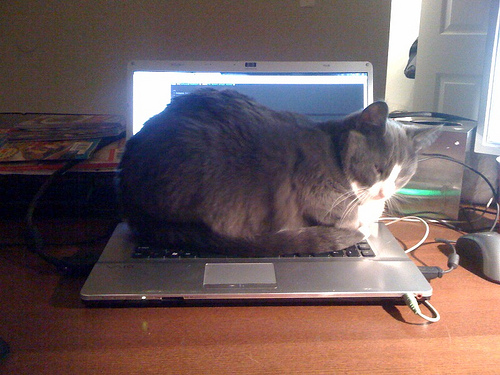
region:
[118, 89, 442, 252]
big cat standing on a laptop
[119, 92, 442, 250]
cat is gray and white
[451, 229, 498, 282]
black and gray mouse of a laptop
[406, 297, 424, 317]
green plug connected to laptop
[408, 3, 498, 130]
white door i the back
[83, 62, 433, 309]
gray laptop on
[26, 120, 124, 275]
black cable of laptop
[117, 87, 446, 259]
cat is lying on a laptop keyboard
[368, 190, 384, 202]
little pinky nose of cat sleeping on a laptop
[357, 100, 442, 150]
two small furry ears of a cat sleeping on a laptop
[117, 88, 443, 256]
white and gray furry cat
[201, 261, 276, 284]
gray laptop mouse pad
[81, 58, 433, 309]
Silver and black laptop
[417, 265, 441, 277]
gray USB plug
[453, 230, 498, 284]
Black and silver computer mouse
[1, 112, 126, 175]
Many different colored magazines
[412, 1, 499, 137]
White interior door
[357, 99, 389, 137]
Furry gray cat ear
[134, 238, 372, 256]
Black laptop computer keys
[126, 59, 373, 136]
Bright Laptop monitor screen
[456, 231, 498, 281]
gray computer mouse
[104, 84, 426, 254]
gray cat sitting on laptop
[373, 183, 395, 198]
white fur on cat's face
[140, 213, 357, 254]
long gray cat's tail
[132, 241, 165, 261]
black computer keys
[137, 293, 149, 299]
white light on computer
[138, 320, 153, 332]
light reflection on desk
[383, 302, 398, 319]
dark shadow from cord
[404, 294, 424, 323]
white cord in computer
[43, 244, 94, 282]
black cord in computer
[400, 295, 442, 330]
cord in the laptop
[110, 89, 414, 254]
cat on the laptop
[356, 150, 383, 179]
eye of the cat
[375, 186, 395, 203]
nose of the cat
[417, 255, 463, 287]
black usb cord in the laptop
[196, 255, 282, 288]
track pad on the laptop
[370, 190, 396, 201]
pink nose of the cat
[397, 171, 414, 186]
eye of the cat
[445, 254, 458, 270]
connector on the usb cord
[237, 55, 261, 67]
webcam on the laptop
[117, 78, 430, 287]
cat on a laptop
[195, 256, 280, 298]
mouse of a laptop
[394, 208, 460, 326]
wires to a laptop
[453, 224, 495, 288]
mouse of a laptop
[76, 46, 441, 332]
cat on a laptop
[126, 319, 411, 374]
wooden desk under laptop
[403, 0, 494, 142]
door to a room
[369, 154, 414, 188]
eyes on a cat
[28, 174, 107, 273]
cable to a laptop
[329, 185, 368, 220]
white whiskers on a cat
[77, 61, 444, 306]
a cat sleeping on a laptop computer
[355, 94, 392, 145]
left ear of the cat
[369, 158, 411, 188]
eyeballs of the cat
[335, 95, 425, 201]
head of the cat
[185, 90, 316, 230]
torso of the cat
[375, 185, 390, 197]
nose of the cat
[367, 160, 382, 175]
one of the cats eyes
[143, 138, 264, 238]
rear legs of the cat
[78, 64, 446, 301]
a grey and white cat laying on a laptop.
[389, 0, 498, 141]
a white wood door that is open.